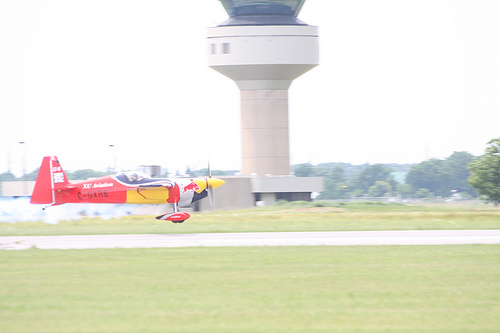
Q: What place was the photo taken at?
A: It was taken at the airport.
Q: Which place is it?
A: It is an airport.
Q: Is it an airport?
A: Yes, it is an airport.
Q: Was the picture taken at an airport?
A: Yes, it was taken in an airport.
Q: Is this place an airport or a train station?
A: It is an airport.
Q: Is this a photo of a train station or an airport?
A: It is showing an airport.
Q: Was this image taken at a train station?
A: No, the picture was taken in an airport.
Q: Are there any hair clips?
A: No, there are no hair clips.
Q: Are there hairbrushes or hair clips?
A: No, there are no hair clips or hairbrushes.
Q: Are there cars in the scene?
A: No, there are no cars.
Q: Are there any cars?
A: No, there are no cars.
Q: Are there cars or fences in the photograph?
A: No, there are no cars or fences.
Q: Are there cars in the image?
A: No, there are no cars.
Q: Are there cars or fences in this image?
A: No, there are no cars or fences.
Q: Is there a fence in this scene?
A: No, there are no fences.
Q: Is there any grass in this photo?
A: Yes, there is grass.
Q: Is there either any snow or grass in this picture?
A: Yes, there is grass.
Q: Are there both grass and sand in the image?
A: No, there is grass but no sand.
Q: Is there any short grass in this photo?
A: Yes, there is short grass.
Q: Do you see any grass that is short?
A: Yes, there is grass that is short.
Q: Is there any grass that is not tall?
A: Yes, there is short grass.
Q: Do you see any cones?
A: No, there are no cones.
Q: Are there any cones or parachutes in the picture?
A: No, there are no cones or parachutes.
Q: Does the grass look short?
A: Yes, the grass is short.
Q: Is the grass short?
A: Yes, the grass is short.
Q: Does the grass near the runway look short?
A: Yes, the grass is short.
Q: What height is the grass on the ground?
A: The grass is short.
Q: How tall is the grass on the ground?
A: The grass is short.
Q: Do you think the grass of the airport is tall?
A: No, the grass is short.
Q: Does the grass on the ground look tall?
A: No, the grass is short.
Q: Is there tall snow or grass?
A: No, there is grass but it is short.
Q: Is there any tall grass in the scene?
A: No, there is grass but it is short.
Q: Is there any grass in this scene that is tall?
A: No, there is grass but it is short.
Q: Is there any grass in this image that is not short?
A: No, there is grass but it is short.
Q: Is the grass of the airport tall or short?
A: The grass is short.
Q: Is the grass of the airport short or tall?
A: The grass is short.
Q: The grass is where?
A: The grass is on the ground.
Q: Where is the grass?
A: The grass is on the ground.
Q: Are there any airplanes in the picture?
A: Yes, there is an airplane.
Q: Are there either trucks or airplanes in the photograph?
A: Yes, there is an airplane.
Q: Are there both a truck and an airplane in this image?
A: No, there is an airplane but no trucks.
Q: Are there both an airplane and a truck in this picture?
A: No, there is an airplane but no trucks.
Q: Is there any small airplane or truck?
A: Yes, there is a small airplane.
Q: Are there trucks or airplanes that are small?
A: Yes, the airplane is small.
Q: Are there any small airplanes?
A: Yes, there is a small airplane.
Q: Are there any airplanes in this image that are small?
A: Yes, there is an airplane that is small.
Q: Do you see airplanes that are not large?
A: Yes, there is a small airplane.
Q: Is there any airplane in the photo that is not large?
A: Yes, there is a small airplane.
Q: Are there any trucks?
A: No, there are no trucks.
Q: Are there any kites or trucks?
A: No, there are no trucks or kites.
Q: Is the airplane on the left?
A: Yes, the airplane is on the left of the image.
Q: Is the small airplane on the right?
A: No, the plane is on the left of the image.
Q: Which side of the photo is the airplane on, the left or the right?
A: The airplane is on the left of the image.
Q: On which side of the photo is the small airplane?
A: The airplane is on the left of the image.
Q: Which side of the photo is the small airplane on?
A: The airplane is on the left of the image.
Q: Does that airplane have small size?
A: Yes, the airplane is small.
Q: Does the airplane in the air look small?
A: Yes, the airplane is small.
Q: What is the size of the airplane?
A: The airplane is small.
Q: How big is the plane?
A: The plane is small.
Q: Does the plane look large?
A: No, the plane is small.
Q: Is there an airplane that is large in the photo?
A: No, there is an airplane but it is small.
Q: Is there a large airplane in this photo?
A: No, there is an airplane but it is small.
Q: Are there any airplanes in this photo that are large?
A: No, there is an airplane but it is small.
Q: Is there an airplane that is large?
A: No, there is an airplane but it is small.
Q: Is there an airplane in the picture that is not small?
A: No, there is an airplane but it is small.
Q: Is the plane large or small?
A: The plane is small.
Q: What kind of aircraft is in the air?
A: The aircraft is an airplane.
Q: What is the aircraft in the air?
A: The aircraft is an airplane.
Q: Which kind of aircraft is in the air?
A: The aircraft is an airplane.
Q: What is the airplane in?
A: The airplane is in the air.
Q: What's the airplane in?
A: The airplane is in the air.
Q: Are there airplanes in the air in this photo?
A: Yes, there is an airplane in the air.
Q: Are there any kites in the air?
A: No, there is an airplane in the air.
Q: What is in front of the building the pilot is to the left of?
A: The airplane is in front of the tower.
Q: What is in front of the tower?
A: The airplane is in front of the tower.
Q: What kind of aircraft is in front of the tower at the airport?
A: The aircraft is an airplane.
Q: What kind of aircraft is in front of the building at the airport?
A: The aircraft is an airplane.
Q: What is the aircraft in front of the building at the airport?
A: The aircraft is an airplane.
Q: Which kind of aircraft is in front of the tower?
A: The aircraft is an airplane.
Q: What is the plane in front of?
A: The plane is in front of the tower.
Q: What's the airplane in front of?
A: The plane is in front of the tower.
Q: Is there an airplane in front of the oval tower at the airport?
A: Yes, there is an airplane in front of the tower.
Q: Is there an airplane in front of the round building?
A: Yes, there is an airplane in front of the tower.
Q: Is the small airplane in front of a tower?
A: Yes, the plane is in front of a tower.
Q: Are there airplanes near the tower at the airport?
A: Yes, there is an airplane near the tower.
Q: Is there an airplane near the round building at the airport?
A: Yes, there is an airplane near the tower.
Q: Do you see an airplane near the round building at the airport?
A: Yes, there is an airplane near the tower.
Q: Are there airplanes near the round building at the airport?
A: Yes, there is an airplane near the tower.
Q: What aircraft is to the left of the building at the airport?
A: The aircraft is an airplane.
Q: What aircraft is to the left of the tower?
A: The aircraft is an airplane.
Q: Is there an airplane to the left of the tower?
A: Yes, there is an airplane to the left of the tower.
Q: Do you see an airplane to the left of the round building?
A: Yes, there is an airplane to the left of the tower.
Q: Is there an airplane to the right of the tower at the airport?
A: No, the airplane is to the left of the tower.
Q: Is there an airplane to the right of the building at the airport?
A: No, the airplane is to the left of the tower.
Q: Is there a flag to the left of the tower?
A: No, there is an airplane to the left of the tower.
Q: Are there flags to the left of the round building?
A: No, there is an airplane to the left of the tower.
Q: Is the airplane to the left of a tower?
A: Yes, the airplane is to the left of a tower.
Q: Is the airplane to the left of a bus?
A: No, the airplane is to the left of a tower.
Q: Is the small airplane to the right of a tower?
A: No, the airplane is to the left of a tower.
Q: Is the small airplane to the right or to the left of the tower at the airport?
A: The airplane is to the left of the tower.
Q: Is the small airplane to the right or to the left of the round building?
A: The airplane is to the left of the tower.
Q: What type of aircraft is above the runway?
A: The aircraft is an airplane.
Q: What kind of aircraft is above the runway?
A: The aircraft is an airplane.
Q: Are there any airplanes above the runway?
A: Yes, there is an airplane above the runway.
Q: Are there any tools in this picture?
A: No, there are no tools.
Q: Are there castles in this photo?
A: No, there are no castles.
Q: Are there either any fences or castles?
A: No, there are no castles or fences.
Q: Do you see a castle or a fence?
A: No, there are no castles or fences.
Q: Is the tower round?
A: Yes, the tower is round.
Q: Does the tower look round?
A: Yes, the tower is round.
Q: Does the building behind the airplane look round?
A: Yes, the tower is round.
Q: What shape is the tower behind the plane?
A: The tower is round.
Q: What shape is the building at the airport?
A: The tower is round.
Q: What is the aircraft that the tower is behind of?
A: The aircraft is an airplane.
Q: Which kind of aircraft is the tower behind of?
A: The tower is behind the airplane.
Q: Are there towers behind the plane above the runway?
A: Yes, there is a tower behind the airplane.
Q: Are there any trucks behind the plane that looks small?
A: No, there is a tower behind the airplane.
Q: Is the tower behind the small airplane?
A: Yes, the tower is behind the airplane.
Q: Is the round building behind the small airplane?
A: Yes, the tower is behind the airplane.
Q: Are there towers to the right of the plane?
A: Yes, there is a tower to the right of the plane.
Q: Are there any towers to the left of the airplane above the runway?
A: No, the tower is to the right of the airplane.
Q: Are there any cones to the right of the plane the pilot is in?
A: No, there is a tower to the right of the plane.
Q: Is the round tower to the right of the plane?
A: Yes, the tower is to the right of the plane.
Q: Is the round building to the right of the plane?
A: Yes, the tower is to the right of the plane.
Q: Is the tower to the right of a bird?
A: No, the tower is to the right of the plane.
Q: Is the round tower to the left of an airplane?
A: No, the tower is to the right of an airplane.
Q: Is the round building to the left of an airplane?
A: No, the tower is to the right of an airplane.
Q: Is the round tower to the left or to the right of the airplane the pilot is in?
A: The tower is to the right of the plane.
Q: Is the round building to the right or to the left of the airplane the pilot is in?
A: The tower is to the right of the plane.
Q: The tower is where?
A: The tower is at the airport.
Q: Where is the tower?
A: The tower is at the airport.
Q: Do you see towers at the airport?
A: Yes, there is a tower at the airport.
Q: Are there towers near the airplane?
A: Yes, there is a tower near the airplane.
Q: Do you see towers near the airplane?
A: Yes, there is a tower near the airplane.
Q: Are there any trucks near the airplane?
A: No, there is a tower near the airplane.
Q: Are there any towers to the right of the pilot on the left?
A: Yes, there is a tower to the right of the pilot.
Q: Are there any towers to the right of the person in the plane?
A: Yes, there is a tower to the right of the pilot.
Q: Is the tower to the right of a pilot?
A: Yes, the tower is to the right of a pilot.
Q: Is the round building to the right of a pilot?
A: Yes, the tower is to the right of a pilot.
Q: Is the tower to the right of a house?
A: No, the tower is to the right of a pilot.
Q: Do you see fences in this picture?
A: No, there are no fences.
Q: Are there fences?
A: No, there are no fences.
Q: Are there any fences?
A: No, there are no fences.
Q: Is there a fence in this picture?
A: No, there are no fences.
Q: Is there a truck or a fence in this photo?
A: No, there are no fences or trucks.